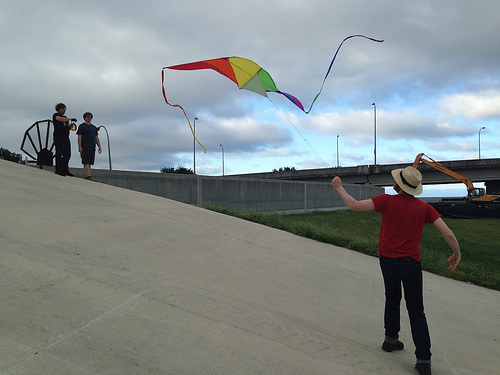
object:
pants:
[53, 136, 70, 171]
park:
[0, 141, 482, 340]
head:
[393, 166, 421, 192]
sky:
[0, 0, 499, 195]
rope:
[266, 97, 334, 176]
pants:
[379, 255, 431, 364]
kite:
[161, 34, 384, 153]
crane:
[412, 153, 500, 208]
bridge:
[235, 158, 500, 195]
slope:
[1, 159, 498, 373]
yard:
[198, 203, 498, 288]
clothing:
[81, 146, 95, 165]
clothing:
[76, 122, 98, 151]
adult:
[53, 103, 77, 177]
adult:
[76, 112, 101, 182]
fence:
[68, 167, 383, 218]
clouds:
[3, 4, 500, 170]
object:
[128, 26, 384, 147]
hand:
[332, 176, 342, 188]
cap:
[391, 166, 423, 195]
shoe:
[415, 363, 432, 374]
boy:
[332, 166, 460, 375]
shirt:
[370, 193, 441, 261]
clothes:
[52, 113, 70, 137]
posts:
[222, 146, 225, 176]